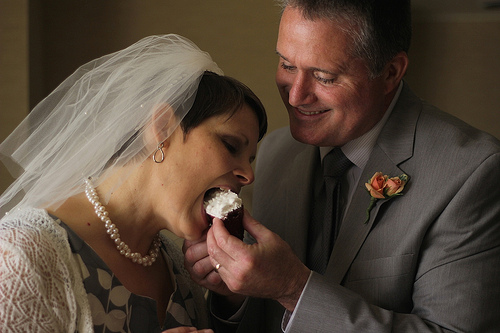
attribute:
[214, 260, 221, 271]
ring — golden, wedding-band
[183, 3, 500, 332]
man — smiling, pictured, groom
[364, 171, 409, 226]
flower — pinned, orange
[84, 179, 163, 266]
necklace — intertwined, pearl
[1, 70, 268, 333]
woman — bride, pictured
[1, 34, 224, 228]
veil — white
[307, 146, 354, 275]
tie — grey, gray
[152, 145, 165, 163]
earring — hoop, silver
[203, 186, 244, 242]
cake — white, sliced, iced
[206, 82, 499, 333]
suit — grey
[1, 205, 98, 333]
sweater — knit, crocheted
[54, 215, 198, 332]
dress — green, floral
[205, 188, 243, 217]
frosting — white